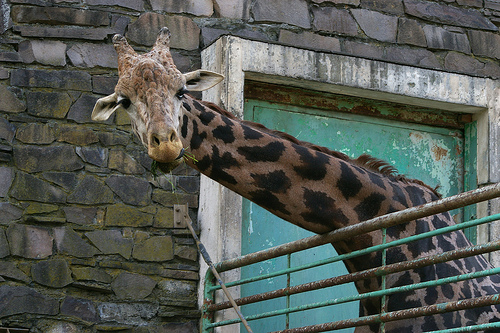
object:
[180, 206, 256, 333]
pole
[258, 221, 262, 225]
paint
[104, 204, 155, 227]
green tiles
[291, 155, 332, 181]
spots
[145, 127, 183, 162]
nose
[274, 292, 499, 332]
bars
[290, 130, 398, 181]
hair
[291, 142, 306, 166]
stripe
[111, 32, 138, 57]
horns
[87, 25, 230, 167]
head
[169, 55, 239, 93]
ear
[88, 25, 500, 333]
giraffe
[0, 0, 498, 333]
wall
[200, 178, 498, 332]
railing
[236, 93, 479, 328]
paint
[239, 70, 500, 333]
door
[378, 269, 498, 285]
paint